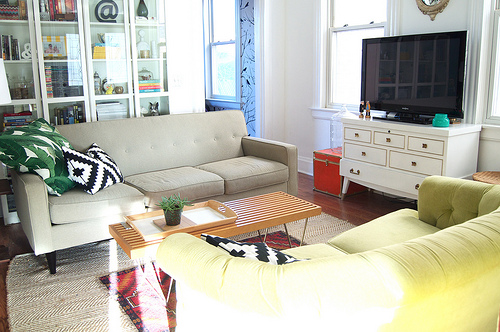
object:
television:
[360, 30, 466, 118]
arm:
[242, 136, 295, 169]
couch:
[10, 110, 297, 275]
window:
[329, 0, 385, 105]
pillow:
[62, 141, 124, 194]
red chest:
[312, 147, 368, 196]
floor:
[296, 168, 321, 199]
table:
[108, 191, 322, 250]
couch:
[153, 176, 497, 332]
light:
[277, 257, 405, 330]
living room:
[0, 2, 500, 332]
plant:
[155, 192, 195, 226]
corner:
[447, 30, 469, 45]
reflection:
[366, 38, 458, 103]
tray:
[124, 200, 238, 242]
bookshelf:
[1, 0, 177, 222]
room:
[3, 0, 496, 330]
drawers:
[339, 110, 482, 204]